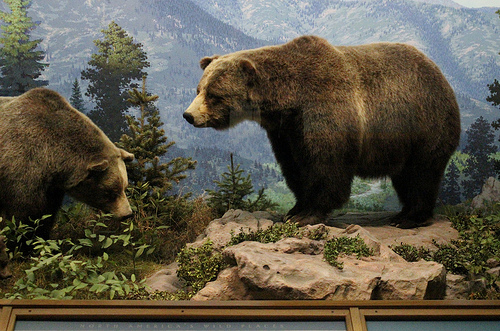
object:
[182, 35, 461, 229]
bear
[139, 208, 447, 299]
rock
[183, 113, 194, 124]
nose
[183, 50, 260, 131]
head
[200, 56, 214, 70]
ear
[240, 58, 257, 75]
ear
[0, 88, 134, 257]
bear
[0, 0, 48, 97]
tree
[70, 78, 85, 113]
tree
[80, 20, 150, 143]
tree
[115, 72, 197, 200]
tree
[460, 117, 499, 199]
tree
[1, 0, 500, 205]
mountains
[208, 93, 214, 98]
eye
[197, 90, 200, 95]
eye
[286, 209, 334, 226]
paw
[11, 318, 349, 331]
placard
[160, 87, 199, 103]
trees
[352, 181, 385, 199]
river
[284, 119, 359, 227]
legs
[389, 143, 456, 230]
legs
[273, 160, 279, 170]
pine tree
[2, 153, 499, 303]
field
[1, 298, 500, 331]
frame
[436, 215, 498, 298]
shrub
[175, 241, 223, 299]
shrub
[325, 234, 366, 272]
ground cover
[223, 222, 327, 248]
ground cover